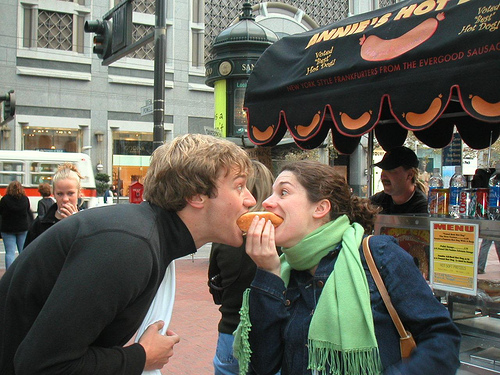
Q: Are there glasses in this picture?
A: No, there are no glasses.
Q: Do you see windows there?
A: Yes, there is a window.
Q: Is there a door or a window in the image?
A: Yes, there is a window.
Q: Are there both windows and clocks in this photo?
A: No, there is a window but no clocks.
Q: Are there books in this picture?
A: No, there are no books.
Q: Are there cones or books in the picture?
A: No, there are no books or cones.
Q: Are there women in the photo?
A: Yes, there is a woman.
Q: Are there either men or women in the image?
A: Yes, there is a woman.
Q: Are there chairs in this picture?
A: No, there are no chairs.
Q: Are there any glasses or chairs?
A: No, there are no chairs or glasses.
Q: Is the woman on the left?
A: Yes, the woman is on the left of the image.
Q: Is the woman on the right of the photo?
A: No, the woman is on the left of the image.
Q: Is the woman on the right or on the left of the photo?
A: The woman is on the left of the image.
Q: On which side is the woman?
A: The woman is on the left of the image.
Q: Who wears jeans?
A: The woman wears jeans.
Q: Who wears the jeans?
A: The woman wears jeans.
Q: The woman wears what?
A: The woman wears jeans.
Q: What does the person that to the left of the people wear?
A: The woman wears jeans.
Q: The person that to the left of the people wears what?
A: The woman wears jeans.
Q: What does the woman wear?
A: The woman wears jeans.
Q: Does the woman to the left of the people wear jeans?
A: Yes, the woman wears jeans.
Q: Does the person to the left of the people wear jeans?
A: Yes, the woman wears jeans.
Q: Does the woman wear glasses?
A: No, the woman wears jeans.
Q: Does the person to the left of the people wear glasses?
A: No, the woman wears jeans.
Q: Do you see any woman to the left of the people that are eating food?
A: Yes, there is a woman to the left of the people.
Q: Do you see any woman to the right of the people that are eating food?
A: No, the woman is to the left of the people.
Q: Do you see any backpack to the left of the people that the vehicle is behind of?
A: No, there is a woman to the left of the people.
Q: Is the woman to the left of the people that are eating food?
A: Yes, the woman is to the left of the people.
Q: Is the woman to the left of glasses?
A: No, the woman is to the left of the people.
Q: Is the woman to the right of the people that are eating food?
A: No, the woman is to the left of the people.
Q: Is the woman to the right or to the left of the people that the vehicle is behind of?
A: The woman is to the left of the people.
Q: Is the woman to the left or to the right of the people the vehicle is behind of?
A: The woman is to the left of the people.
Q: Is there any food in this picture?
A: Yes, there is food.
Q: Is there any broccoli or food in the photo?
A: Yes, there is food.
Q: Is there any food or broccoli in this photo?
A: Yes, there is food.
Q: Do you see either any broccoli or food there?
A: Yes, there is food.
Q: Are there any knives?
A: No, there are no knives.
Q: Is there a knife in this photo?
A: No, there are no knives.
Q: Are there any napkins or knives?
A: No, there are no knives or napkins.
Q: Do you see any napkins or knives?
A: No, there are no knives or napkins.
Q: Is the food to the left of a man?
A: No, the food is to the right of a man.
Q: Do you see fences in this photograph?
A: No, there are no fences.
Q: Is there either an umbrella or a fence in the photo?
A: No, there are no fences or umbrellas.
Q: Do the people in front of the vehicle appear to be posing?
A: Yes, the people are posing.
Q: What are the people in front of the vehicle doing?
A: The people are posing.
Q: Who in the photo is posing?
A: The people are posing.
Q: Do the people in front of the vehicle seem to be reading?
A: No, the people are posing.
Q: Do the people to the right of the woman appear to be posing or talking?
A: The people are posing.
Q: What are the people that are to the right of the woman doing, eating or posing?
A: The people are posing.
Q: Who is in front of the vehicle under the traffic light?
A: The people are in front of the vehicle.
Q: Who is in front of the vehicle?
A: The people are in front of the vehicle.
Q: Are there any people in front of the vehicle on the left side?
A: Yes, there are people in front of the vehicle.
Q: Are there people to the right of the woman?
A: Yes, there are people to the right of the woman.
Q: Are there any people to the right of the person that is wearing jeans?
A: Yes, there are people to the right of the woman.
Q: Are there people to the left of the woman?
A: No, the people are to the right of the woman.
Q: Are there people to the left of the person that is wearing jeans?
A: No, the people are to the right of the woman.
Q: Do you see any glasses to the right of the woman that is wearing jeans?
A: No, there are people to the right of the woman.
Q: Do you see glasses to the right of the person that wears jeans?
A: No, there are people to the right of the woman.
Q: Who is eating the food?
A: The people are eating the food.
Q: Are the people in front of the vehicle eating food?
A: Yes, the people are eating food.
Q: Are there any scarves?
A: Yes, there is a scarf.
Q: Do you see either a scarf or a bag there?
A: Yes, there is a scarf.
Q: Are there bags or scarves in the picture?
A: Yes, there is a scarf.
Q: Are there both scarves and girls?
A: Yes, there are both a scarf and a girl.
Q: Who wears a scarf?
A: The girl wears a scarf.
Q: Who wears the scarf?
A: The girl wears a scarf.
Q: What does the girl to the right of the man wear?
A: The girl wears a scarf.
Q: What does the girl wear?
A: The girl wears a scarf.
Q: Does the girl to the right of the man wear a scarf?
A: Yes, the girl wears a scarf.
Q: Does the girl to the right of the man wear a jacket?
A: No, the girl wears a scarf.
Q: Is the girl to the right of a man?
A: Yes, the girl is to the right of a man.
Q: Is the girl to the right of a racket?
A: No, the girl is to the right of a man.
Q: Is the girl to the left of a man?
A: No, the girl is to the right of a man.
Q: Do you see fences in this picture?
A: No, there are no fences.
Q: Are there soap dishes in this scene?
A: No, there are no soap dishes.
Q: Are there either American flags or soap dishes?
A: No, there are no soap dishes or American flags.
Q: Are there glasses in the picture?
A: No, there are no glasses.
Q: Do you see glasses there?
A: No, there are no glasses.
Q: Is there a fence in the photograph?
A: No, there are no fences.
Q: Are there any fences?
A: No, there are no fences.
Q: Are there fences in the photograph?
A: No, there are no fences.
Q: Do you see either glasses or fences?
A: No, there are no fences or glasses.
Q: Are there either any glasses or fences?
A: No, there are no fences or glasses.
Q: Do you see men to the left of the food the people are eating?
A: Yes, there is a man to the left of the food.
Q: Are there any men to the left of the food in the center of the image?
A: Yes, there is a man to the left of the food.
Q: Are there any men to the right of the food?
A: No, the man is to the left of the food.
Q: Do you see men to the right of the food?
A: No, the man is to the left of the food.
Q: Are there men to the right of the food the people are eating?
A: No, the man is to the left of the food.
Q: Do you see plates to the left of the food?
A: No, there is a man to the left of the food.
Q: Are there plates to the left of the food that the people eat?
A: No, there is a man to the left of the food.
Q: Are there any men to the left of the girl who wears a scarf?
A: Yes, there is a man to the left of the girl.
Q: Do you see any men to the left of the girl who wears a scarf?
A: Yes, there is a man to the left of the girl.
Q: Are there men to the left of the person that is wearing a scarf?
A: Yes, there is a man to the left of the girl.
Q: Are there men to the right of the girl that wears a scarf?
A: No, the man is to the left of the girl.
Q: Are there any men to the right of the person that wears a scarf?
A: No, the man is to the left of the girl.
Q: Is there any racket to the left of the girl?
A: No, there is a man to the left of the girl.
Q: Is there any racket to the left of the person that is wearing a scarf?
A: No, there is a man to the left of the girl.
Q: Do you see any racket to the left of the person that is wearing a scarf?
A: No, there is a man to the left of the girl.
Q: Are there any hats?
A: Yes, there is a hat.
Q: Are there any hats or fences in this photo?
A: Yes, there is a hat.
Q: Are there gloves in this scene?
A: No, there are no gloves.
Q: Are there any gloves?
A: No, there are no gloves.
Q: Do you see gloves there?
A: No, there are no gloves.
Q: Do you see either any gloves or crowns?
A: No, there are no gloves or crowns.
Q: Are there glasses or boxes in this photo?
A: No, there are no glasses or boxes.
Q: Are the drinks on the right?
A: Yes, the drinks are on the right of the image.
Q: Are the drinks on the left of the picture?
A: No, the drinks are on the right of the image.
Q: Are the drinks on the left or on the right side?
A: The drinks are on the right of the image.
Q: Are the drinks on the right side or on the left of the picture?
A: The drinks are on the right of the image.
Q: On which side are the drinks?
A: The drinks are on the right of the image.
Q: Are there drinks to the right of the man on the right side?
A: Yes, there are drinks to the right of the man.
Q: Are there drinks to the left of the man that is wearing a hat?
A: No, the drinks are to the right of the man.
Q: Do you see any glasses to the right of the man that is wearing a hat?
A: No, there are drinks to the right of the man.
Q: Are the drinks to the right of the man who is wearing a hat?
A: Yes, the drinks are to the right of the man.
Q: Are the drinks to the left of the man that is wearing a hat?
A: No, the drinks are to the right of the man.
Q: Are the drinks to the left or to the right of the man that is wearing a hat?
A: The drinks are to the right of the man.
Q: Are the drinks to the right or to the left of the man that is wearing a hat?
A: The drinks are to the right of the man.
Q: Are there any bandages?
A: No, there are no bandages.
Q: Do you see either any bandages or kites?
A: No, there are no bandages or kites.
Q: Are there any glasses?
A: No, there are no glasses.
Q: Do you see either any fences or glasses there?
A: No, there are no glasses or fences.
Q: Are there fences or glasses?
A: No, there are no glasses or fences.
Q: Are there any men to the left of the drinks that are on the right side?
A: Yes, there is a man to the left of the drinks.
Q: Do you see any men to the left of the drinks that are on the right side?
A: Yes, there is a man to the left of the drinks.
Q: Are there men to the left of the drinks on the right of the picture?
A: Yes, there is a man to the left of the drinks.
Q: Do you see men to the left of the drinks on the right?
A: Yes, there is a man to the left of the drinks.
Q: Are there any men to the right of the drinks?
A: No, the man is to the left of the drinks.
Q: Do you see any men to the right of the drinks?
A: No, the man is to the left of the drinks.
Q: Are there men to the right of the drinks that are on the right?
A: No, the man is to the left of the drinks.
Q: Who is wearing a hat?
A: The man is wearing a hat.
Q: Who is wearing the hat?
A: The man is wearing a hat.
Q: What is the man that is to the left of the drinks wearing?
A: The man is wearing a hat.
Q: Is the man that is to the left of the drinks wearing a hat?
A: Yes, the man is wearing a hat.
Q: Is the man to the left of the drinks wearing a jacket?
A: No, the man is wearing a hat.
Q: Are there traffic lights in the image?
A: Yes, there is a traffic light.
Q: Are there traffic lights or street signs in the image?
A: Yes, there is a traffic light.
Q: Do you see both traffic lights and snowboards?
A: No, there is a traffic light but no snowboards.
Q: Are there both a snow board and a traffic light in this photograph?
A: No, there is a traffic light but no snowboards.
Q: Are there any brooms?
A: No, there are no brooms.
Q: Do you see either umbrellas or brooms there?
A: No, there are no brooms or umbrellas.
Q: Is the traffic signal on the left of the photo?
A: Yes, the traffic signal is on the left of the image.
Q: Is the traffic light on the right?
A: No, the traffic light is on the left of the image.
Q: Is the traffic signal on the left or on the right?
A: The traffic signal is on the left of the image.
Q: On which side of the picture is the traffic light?
A: The traffic light is on the left of the image.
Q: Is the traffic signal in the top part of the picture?
A: Yes, the traffic signal is in the top of the image.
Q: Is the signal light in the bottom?
A: No, the signal light is in the top of the image.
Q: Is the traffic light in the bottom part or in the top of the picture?
A: The traffic light is in the top of the image.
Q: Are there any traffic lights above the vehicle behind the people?
A: Yes, there is a traffic light above the vehicle.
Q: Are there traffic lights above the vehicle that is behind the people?
A: Yes, there is a traffic light above the vehicle.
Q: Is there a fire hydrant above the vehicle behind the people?
A: No, there is a traffic light above the vehicle.